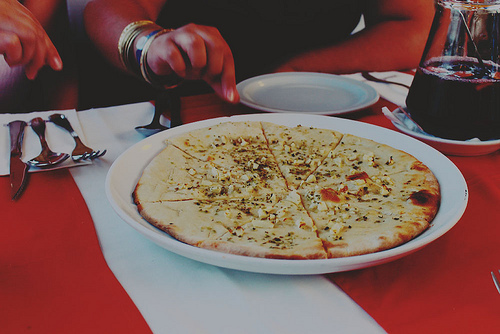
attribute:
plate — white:
[104, 108, 472, 277]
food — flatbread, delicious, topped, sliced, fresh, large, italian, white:
[133, 117, 442, 259]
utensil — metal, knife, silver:
[7, 118, 27, 201]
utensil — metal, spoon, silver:
[26, 116, 69, 177]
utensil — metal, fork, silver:
[49, 112, 105, 163]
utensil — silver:
[134, 93, 166, 137]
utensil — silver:
[168, 90, 185, 129]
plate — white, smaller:
[230, 70, 382, 118]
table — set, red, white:
[0, 68, 499, 333]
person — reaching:
[81, 0, 456, 104]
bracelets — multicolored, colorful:
[116, 18, 176, 92]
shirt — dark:
[155, 1, 367, 83]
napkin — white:
[1, 107, 91, 177]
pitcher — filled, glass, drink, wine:
[403, 2, 498, 142]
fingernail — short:
[225, 86, 238, 105]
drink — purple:
[404, 54, 500, 143]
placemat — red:
[0, 168, 151, 332]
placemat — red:
[145, 69, 499, 333]